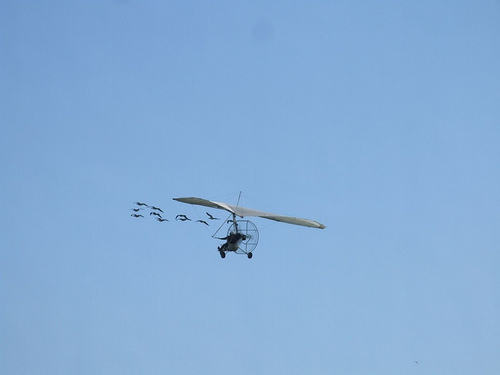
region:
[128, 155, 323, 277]
A plane flying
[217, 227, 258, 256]
A man on the plane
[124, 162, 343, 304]
A small plane in the air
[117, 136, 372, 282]
A plane flying low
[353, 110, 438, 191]
Clear blue skies in the photo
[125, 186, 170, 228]
Birds in the air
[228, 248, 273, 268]
Wheels on the plane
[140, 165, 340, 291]
A small plane in the photo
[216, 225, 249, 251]
A pilot in the plane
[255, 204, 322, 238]
Wings on the plane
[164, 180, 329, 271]
ultra light aircraft in sky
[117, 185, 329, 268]
aircraft being followed by birds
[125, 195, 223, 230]
birds following small aircraft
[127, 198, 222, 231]
flock of birds in sky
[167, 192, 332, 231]
top wing of ultra light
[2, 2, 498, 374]
clear blue cloudless sky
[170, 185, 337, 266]
single seat aircraft in sky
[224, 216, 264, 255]
large fan area of ultra light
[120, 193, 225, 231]
birds flying near craft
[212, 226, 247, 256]
person sitting in aircraft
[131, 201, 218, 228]
Black birds flying with plane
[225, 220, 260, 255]
Round propeller on plane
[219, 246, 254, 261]
Two fron wheels on the plane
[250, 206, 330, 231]
Right wing of the plane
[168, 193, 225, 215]
Left wing of the plane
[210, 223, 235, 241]
Man flying the plane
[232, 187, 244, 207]
Bar at the top of the wings of plane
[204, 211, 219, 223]
Bird with its wings wide open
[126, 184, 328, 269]
Man flying a plane with birds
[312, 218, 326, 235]
Dark grey end of right wing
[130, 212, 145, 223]
the black bird flying in the sky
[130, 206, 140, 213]
the black bird flying in the sky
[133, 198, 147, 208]
the black bird flying in the sky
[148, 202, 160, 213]
the black bird flying in the sky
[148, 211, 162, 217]
the black bird flying in the sky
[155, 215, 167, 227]
the black bird flying in the sky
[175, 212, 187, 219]
the black bird flying in the sky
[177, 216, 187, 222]
the black bird flying in the sky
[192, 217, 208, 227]
the black bird flying in the sky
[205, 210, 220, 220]
the black bird flying in the sky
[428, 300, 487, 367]
part of the clear blue sky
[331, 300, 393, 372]
part of the clear blue sky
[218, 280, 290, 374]
part of the clear blue sky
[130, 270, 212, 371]
part of the clear blue sky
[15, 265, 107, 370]
part of the clear blue sky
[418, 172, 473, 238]
part of the clear blue sky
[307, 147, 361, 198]
part of the clear blue sky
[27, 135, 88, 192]
part of the clear blue sky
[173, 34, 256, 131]
part of the clear blue sky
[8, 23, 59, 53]
part of the clear blue sky